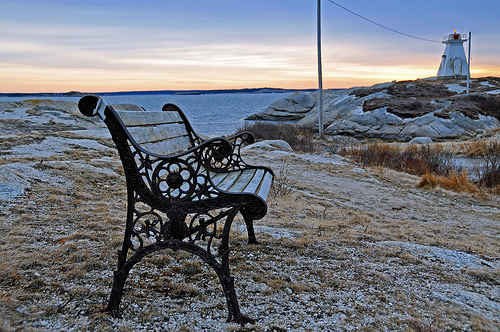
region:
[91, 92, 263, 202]
bench has ice and snow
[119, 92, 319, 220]
bench made of wood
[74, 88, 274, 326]
bench's side and base made of wood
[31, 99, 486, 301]
the grass is brown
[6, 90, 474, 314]
snow is on grass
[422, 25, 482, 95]
white building in background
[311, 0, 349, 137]
electrical pole near bench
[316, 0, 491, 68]
electrical wire going to other pole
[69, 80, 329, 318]
the bench is empty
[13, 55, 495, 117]
the sky is orange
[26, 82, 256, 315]
the bench is metal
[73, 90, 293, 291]
the bench seat is wooden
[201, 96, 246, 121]
the water is still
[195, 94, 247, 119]
the water is calm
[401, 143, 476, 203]
the grass is brown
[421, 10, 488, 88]
the tower is distant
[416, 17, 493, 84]
the tower is white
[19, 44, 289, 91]
the sky is pretty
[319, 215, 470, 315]
the gravel is on the ground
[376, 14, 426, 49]
the wire is thick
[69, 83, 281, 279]
bench on the ground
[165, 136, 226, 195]
black arm of bench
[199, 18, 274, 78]
sky above the land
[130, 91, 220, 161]
back of the bench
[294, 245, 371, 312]
rocks on the ground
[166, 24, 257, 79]
clouds in the sky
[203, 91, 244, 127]
water in the distance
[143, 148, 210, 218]
design on bench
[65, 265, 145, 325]
back leg of the bench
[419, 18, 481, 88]
structure in the background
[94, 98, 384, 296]
a bench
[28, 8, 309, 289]
a bench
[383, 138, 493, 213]
patch of dead grass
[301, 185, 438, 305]
iced snow on the ground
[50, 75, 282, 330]
frost on a bench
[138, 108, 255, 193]
wooden panels on a bench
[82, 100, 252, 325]
black metal bench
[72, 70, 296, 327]
a bench by the sea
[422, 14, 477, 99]
a light house by the ocean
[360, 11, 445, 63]
a wire in the sky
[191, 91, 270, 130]
the dark blue ocean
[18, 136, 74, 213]
rocks between the grass